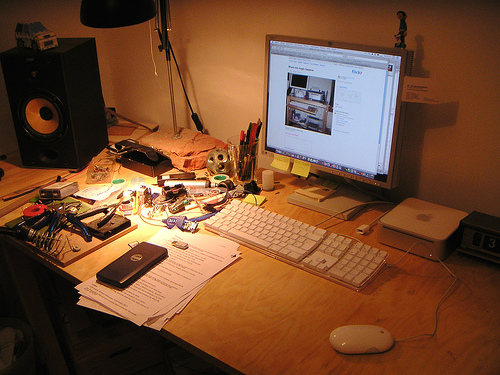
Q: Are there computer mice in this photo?
A: Yes, there is a computer mouse.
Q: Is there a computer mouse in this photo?
A: Yes, there is a computer mouse.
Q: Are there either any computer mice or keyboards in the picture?
A: Yes, there is a computer mouse.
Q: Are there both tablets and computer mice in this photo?
A: No, there is a computer mouse but no tablets.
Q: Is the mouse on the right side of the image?
A: Yes, the mouse is on the right of the image.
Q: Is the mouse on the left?
A: No, the mouse is on the right of the image.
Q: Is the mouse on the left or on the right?
A: The mouse is on the right of the image.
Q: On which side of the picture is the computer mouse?
A: The computer mouse is on the right of the image.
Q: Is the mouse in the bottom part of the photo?
A: Yes, the mouse is in the bottom of the image.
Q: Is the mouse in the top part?
A: No, the mouse is in the bottom of the image.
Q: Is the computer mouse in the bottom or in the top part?
A: The computer mouse is in the bottom of the image.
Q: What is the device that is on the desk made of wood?
A: The device is a computer mouse.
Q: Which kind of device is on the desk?
A: The device is a computer mouse.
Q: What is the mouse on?
A: The mouse is on the desk.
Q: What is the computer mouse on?
A: The mouse is on the desk.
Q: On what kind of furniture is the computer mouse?
A: The computer mouse is on the desk.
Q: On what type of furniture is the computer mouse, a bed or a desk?
A: The computer mouse is on a desk.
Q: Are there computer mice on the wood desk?
A: Yes, there is a computer mouse on the desk.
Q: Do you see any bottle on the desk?
A: No, there is a computer mouse on the desk.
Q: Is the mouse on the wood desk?
A: Yes, the mouse is on the desk.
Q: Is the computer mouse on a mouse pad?
A: No, the computer mouse is on the desk.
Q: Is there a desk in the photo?
A: Yes, there is a desk.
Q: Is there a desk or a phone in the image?
A: Yes, there is a desk.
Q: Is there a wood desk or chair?
A: Yes, there is a wood desk.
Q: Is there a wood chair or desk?
A: Yes, there is a wood desk.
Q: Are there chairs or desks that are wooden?
A: Yes, the desk is wooden.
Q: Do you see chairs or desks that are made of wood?
A: Yes, the desk is made of wood.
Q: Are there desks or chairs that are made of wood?
A: Yes, the desk is made of wood.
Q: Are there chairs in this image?
A: No, there are no chairs.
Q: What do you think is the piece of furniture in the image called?
A: The piece of furniture is a desk.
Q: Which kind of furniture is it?
A: The piece of furniture is a desk.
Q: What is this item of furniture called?
A: This is a desk.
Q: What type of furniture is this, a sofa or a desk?
A: This is a desk.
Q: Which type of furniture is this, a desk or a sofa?
A: This is a desk.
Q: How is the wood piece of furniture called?
A: The piece of furniture is a desk.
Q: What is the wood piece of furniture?
A: The piece of furniture is a desk.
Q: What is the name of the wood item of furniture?
A: The piece of furniture is a desk.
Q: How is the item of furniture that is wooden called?
A: The piece of furniture is a desk.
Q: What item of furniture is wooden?
A: The piece of furniture is a desk.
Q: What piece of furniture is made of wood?
A: The piece of furniture is a desk.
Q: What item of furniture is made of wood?
A: The piece of furniture is a desk.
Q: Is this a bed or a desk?
A: This is a desk.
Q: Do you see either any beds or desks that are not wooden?
A: No, there is a desk but it is wooden.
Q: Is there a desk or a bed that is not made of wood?
A: No, there is a desk but it is made of wood.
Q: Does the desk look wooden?
A: Yes, the desk is wooden.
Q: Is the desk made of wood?
A: Yes, the desk is made of wood.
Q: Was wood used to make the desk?
A: Yes, the desk is made of wood.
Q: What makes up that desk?
A: The desk is made of wood.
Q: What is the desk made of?
A: The desk is made of wood.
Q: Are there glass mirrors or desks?
A: No, there is a desk but it is wooden.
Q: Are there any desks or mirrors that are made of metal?
A: No, there is a desk but it is made of wood.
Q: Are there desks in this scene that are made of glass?
A: No, there is a desk but it is made of wood.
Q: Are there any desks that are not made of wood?
A: No, there is a desk but it is made of wood.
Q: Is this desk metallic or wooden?
A: The desk is wooden.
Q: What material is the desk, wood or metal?
A: The desk is made of wood.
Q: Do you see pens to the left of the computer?
A: Yes, there are pens to the left of the computer.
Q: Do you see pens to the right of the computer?
A: No, the pens are to the left of the computer.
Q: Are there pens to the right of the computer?
A: No, the pens are to the left of the computer.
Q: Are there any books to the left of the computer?
A: No, there are pens to the left of the computer.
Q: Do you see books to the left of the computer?
A: No, there are pens to the left of the computer.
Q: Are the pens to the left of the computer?
A: Yes, the pens are to the left of the computer.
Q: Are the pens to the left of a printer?
A: No, the pens are to the left of the computer.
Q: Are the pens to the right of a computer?
A: No, the pens are to the left of a computer.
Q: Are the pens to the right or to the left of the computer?
A: The pens are to the left of the computer.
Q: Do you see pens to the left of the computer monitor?
A: Yes, there are pens to the left of the computer monitor.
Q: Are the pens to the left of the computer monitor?
A: Yes, the pens are to the left of the computer monitor.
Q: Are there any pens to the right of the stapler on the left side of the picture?
A: Yes, there are pens to the right of the stapler.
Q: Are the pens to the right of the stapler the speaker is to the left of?
A: Yes, the pens are to the right of the stapler.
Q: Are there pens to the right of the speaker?
A: Yes, there are pens to the right of the speaker.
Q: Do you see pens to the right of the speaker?
A: Yes, there are pens to the right of the speaker.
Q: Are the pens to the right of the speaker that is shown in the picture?
A: Yes, the pens are to the right of the speaker.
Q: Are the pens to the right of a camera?
A: No, the pens are to the right of the speaker.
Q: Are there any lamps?
A: Yes, there is a lamp.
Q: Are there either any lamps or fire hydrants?
A: Yes, there is a lamp.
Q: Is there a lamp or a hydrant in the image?
A: Yes, there is a lamp.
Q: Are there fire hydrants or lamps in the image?
A: Yes, there is a lamp.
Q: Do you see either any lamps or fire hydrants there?
A: Yes, there is a lamp.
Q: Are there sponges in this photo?
A: No, there are no sponges.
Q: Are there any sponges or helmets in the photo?
A: No, there are no sponges or helmets.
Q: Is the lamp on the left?
A: Yes, the lamp is on the left of the image.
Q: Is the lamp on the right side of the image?
A: No, the lamp is on the left of the image.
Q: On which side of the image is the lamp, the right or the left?
A: The lamp is on the left of the image.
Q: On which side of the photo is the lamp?
A: The lamp is on the left of the image.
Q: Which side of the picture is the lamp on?
A: The lamp is on the left of the image.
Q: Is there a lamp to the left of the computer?
A: Yes, there is a lamp to the left of the computer.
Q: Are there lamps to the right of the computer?
A: No, the lamp is to the left of the computer.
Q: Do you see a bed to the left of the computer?
A: No, there is a lamp to the left of the computer.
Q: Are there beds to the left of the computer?
A: No, there is a lamp to the left of the computer.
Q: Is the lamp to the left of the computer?
A: Yes, the lamp is to the left of the computer.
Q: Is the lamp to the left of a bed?
A: No, the lamp is to the left of the computer.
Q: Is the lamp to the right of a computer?
A: No, the lamp is to the left of a computer.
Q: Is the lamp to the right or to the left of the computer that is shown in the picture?
A: The lamp is to the left of the computer.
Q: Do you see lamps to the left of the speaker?
A: No, the lamp is to the right of the speaker.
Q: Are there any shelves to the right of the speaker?
A: No, there is a lamp to the right of the speaker.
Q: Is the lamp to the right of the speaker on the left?
A: Yes, the lamp is to the right of the speaker.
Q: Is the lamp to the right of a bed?
A: No, the lamp is to the right of the speaker.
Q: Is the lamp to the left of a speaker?
A: No, the lamp is to the right of a speaker.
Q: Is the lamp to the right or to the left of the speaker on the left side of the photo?
A: The lamp is to the right of the speaker.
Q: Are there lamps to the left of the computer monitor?
A: Yes, there is a lamp to the left of the computer monitor.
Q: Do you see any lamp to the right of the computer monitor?
A: No, the lamp is to the left of the computer monitor.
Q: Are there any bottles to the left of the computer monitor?
A: No, there is a lamp to the left of the computer monitor.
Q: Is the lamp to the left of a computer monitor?
A: Yes, the lamp is to the left of a computer monitor.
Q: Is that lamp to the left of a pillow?
A: No, the lamp is to the left of a computer monitor.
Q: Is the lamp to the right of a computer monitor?
A: No, the lamp is to the left of a computer monitor.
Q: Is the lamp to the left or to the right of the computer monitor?
A: The lamp is to the left of the computer monitor.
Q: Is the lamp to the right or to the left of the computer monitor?
A: The lamp is to the left of the computer monitor.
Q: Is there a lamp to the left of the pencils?
A: Yes, there is a lamp to the left of the pencils.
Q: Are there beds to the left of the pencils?
A: No, there is a lamp to the left of the pencils.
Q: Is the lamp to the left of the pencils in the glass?
A: Yes, the lamp is to the left of the pencils.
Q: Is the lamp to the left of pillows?
A: No, the lamp is to the left of the pencils.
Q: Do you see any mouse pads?
A: No, there are no mouse pads.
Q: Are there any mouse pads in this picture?
A: No, there are no mouse pads.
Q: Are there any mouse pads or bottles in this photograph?
A: No, there are no mouse pads or bottles.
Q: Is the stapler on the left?
A: Yes, the stapler is on the left of the image.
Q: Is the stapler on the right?
A: No, the stapler is on the left of the image.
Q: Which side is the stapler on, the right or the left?
A: The stapler is on the left of the image.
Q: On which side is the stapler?
A: The stapler is on the left of the image.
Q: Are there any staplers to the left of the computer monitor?
A: Yes, there is a stapler to the left of the computer monitor.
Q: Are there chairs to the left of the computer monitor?
A: No, there is a stapler to the left of the computer monitor.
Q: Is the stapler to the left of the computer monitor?
A: Yes, the stapler is to the left of the computer monitor.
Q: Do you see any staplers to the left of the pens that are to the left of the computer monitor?
A: Yes, there is a stapler to the left of the pens.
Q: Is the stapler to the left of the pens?
A: Yes, the stapler is to the left of the pens.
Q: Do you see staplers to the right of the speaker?
A: Yes, there is a stapler to the right of the speaker.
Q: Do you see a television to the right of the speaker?
A: No, there is a stapler to the right of the speaker.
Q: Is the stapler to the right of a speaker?
A: Yes, the stapler is to the right of a speaker.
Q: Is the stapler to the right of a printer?
A: No, the stapler is to the right of a speaker.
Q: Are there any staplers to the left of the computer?
A: Yes, there is a stapler to the left of the computer.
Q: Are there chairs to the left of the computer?
A: No, there is a stapler to the left of the computer.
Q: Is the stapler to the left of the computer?
A: Yes, the stapler is to the left of the computer.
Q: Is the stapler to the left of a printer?
A: No, the stapler is to the left of the computer.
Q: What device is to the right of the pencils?
A: The device is a computer monitor.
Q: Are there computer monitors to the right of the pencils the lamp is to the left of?
A: Yes, there is a computer monitor to the right of the pencils.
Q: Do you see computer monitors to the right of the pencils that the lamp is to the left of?
A: Yes, there is a computer monitor to the right of the pencils.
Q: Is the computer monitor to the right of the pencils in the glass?
A: Yes, the computer monitor is to the right of the pencils.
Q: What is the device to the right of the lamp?
A: The device is a computer monitor.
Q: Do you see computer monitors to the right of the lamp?
A: Yes, there is a computer monitor to the right of the lamp.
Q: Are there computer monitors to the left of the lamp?
A: No, the computer monitor is to the right of the lamp.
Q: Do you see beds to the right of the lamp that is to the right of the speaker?
A: No, there is a computer monitor to the right of the lamp.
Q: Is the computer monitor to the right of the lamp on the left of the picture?
A: Yes, the computer monitor is to the right of the lamp.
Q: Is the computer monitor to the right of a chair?
A: No, the computer monitor is to the right of the lamp.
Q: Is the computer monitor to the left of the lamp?
A: No, the computer monitor is to the right of the lamp.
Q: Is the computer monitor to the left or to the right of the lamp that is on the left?
A: The computer monitor is to the right of the lamp.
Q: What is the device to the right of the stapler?
A: The device is a computer monitor.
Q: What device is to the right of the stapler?
A: The device is a computer monitor.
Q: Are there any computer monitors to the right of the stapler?
A: Yes, there is a computer monitor to the right of the stapler.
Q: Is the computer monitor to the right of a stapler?
A: Yes, the computer monitor is to the right of a stapler.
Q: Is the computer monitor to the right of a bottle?
A: No, the computer monitor is to the right of a stapler.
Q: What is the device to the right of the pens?
A: The device is a computer monitor.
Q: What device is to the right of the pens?
A: The device is a computer monitor.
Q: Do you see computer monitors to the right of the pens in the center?
A: Yes, there is a computer monitor to the right of the pens.